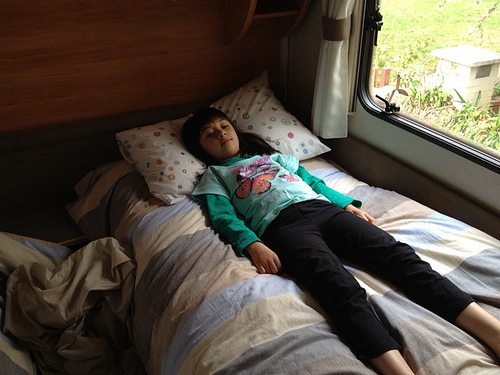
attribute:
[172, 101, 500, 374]
she — lying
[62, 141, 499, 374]
bed — striped, hers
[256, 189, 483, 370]
pants — black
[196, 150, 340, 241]
shirt — blue, short sleeve, long sleeve, long sleeved, green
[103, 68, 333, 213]
case — white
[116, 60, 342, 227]
pillowcase — white, colorful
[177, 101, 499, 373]
girl — little, lying, laying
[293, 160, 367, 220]
sleeve — green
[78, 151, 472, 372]
spread — striped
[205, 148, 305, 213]
design — butterfly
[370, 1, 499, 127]
plants — green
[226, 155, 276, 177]
writing — pink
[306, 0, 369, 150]
curtains — white, hanging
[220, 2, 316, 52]
shelf — small, wooden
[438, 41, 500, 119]
wall — cement, little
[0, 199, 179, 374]
blankets — piled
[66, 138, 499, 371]
bedspread — nice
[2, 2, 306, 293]
walls — wood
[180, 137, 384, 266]
top — green